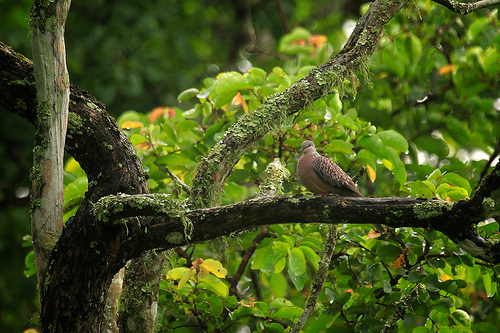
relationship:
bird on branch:
[291, 137, 370, 201] [169, 187, 486, 252]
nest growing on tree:
[92, 192, 180, 221] [3, 2, 499, 330]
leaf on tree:
[311, 31, 356, 59] [191, 40, 468, 292]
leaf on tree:
[370, 137, 408, 187] [3, 2, 499, 330]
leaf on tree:
[341, 95, 430, 187] [306, 100, 448, 177]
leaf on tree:
[268, 302, 305, 320] [3, 2, 499, 330]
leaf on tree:
[184, 255, 226, 283] [3, 2, 499, 330]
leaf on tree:
[163, 262, 190, 283] [3, 2, 499, 330]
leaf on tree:
[288, 247, 308, 276] [3, 2, 499, 330]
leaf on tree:
[359, 131, 392, 162] [127, 1, 497, 330]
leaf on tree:
[377, 128, 409, 155] [3, 2, 499, 330]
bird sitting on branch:
[291, 137, 370, 201] [170, 198, 464, 237]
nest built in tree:
[103, 192, 181, 216] [36, 62, 453, 269]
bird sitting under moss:
[297, 140, 360, 198] [189, 61, 354, 209]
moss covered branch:
[189, 61, 354, 209] [192, 0, 406, 213]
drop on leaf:
[308, 91, 339, 129] [383, 149, 410, 189]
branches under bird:
[218, 227, 499, 329] [291, 133, 362, 197]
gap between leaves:
[416, 134, 483, 159] [359, 56, 498, 194]